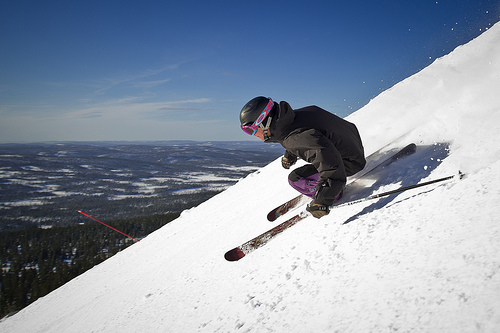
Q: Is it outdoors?
A: Yes, it is outdoors.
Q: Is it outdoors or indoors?
A: It is outdoors.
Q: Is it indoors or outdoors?
A: It is outdoors.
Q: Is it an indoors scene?
A: No, it is outdoors.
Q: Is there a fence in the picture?
A: No, there are no fences.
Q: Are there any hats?
A: Yes, there is a hat.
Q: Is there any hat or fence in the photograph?
A: Yes, there is a hat.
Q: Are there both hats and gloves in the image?
A: Yes, there are both a hat and gloves.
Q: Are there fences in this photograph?
A: No, there are no fences.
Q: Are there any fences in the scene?
A: No, there are no fences.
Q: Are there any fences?
A: No, there are no fences.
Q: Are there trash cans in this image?
A: No, there are no trash cans.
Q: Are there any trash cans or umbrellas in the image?
A: No, there are no trash cans or umbrellas.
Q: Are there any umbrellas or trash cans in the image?
A: No, there are no trash cans or umbrellas.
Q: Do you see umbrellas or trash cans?
A: No, there are no trash cans or umbrellas.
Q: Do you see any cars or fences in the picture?
A: No, there are no fences or cars.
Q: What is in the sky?
A: The clouds are in the sky.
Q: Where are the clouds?
A: The clouds are in the sky.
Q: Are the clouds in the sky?
A: Yes, the clouds are in the sky.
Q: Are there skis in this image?
A: Yes, there are skis.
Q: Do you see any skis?
A: Yes, there are skis.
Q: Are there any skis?
A: Yes, there are skis.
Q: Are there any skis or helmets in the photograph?
A: Yes, there are skis.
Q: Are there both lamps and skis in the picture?
A: No, there are skis but no lamps.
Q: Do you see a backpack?
A: No, there are no backpacks.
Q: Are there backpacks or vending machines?
A: No, there are no backpacks or vending machines.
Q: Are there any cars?
A: No, there are no cars.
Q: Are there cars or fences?
A: No, there are no cars or fences.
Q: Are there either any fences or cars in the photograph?
A: No, there are no cars or fences.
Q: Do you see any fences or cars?
A: No, there are no cars or fences.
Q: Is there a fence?
A: No, there are no fences.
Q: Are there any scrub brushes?
A: No, there are no scrub brushes.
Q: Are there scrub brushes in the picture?
A: No, there are no scrub brushes.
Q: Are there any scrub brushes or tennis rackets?
A: No, there are no scrub brushes or tennis rackets.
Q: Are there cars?
A: No, there are no cars.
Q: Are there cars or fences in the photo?
A: No, there are no cars or fences.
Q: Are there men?
A: No, there are no men.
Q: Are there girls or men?
A: No, there are no men or girls.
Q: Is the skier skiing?
A: Yes, the skier is skiing.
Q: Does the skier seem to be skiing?
A: Yes, the skier is skiing.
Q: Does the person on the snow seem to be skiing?
A: Yes, the skier is skiing.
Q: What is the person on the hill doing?
A: The skier is skiing.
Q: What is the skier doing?
A: The skier is skiing.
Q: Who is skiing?
A: The skier is skiing.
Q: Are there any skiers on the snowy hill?
A: Yes, there is a skier on the hill.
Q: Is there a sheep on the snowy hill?
A: No, there is a skier on the hill.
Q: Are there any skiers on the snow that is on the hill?
A: Yes, there is a skier on the snow.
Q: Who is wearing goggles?
A: The skier is wearing goggles.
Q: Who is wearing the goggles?
A: The skier is wearing goggles.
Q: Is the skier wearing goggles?
A: Yes, the skier is wearing goggles.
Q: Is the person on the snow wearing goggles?
A: Yes, the skier is wearing goggles.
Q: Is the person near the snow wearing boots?
A: No, the skier is wearing goggles.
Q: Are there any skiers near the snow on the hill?
A: Yes, there is a skier near the snow.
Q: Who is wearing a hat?
A: The skier is wearing a hat.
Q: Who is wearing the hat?
A: The skier is wearing a hat.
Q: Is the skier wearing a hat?
A: Yes, the skier is wearing a hat.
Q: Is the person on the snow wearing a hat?
A: Yes, the skier is wearing a hat.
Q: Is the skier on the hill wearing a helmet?
A: No, the skier is wearing a hat.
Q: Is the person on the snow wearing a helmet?
A: No, the skier is wearing a hat.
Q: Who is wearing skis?
A: The skier is wearing skis.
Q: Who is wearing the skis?
A: The skier is wearing skis.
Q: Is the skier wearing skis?
A: Yes, the skier is wearing skis.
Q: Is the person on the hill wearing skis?
A: Yes, the skier is wearing skis.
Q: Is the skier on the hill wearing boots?
A: No, the skier is wearing skis.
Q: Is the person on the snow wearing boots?
A: No, the skier is wearing skis.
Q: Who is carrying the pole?
A: The skier is carrying the pole.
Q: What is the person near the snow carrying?
A: The skier is carrying a pole.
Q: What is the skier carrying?
A: The skier is carrying a pole.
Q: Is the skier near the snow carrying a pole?
A: Yes, the skier is carrying a pole.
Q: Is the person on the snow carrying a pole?
A: Yes, the skier is carrying a pole.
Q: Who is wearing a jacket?
A: The skier is wearing a jacket.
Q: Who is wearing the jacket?
A: The skier is wearing a jacket.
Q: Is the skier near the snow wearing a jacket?
A: Yes, the skier is wearing a jacket.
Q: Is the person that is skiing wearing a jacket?
A: Yes, the skier is wearing a jacket.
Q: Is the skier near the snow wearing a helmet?
A: No, the skier is wearing a jacket.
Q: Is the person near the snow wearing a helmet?
A: No, the skier is wearing a jacket.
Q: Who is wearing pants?
A: The skier is wearing pants.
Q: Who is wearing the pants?
A: The skier is wearing pants.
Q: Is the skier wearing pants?
A: Yes, the skier is wearing pants.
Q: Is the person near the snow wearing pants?
A: Yes, the skier is wearing pants.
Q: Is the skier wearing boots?
A: No, the skier is wearing pants.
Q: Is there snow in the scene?
A: Yes, there is snow.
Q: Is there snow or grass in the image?
A: Yes, there is snow.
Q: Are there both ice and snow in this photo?
A: No, there is snow but no ice.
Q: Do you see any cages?
A: No, there are no cages.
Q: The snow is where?
A: The snow is on the hill.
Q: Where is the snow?
A: The snow is on the hill.